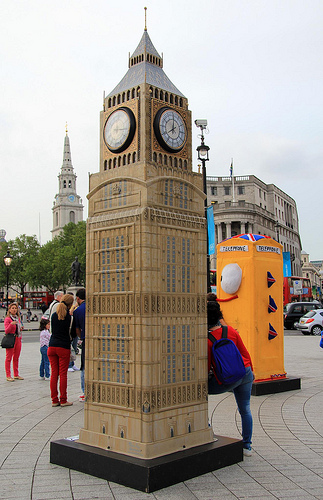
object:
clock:
[153, 105, 189, 154]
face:
[216, 236, 252, 356]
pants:
[46, 345, 71, 406]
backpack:
[207, 325, 246, 393]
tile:
[0, 462, 36, 471]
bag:
[0, 324, 17, 351]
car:
[294, 306, 323, 337]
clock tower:
[49, 3, 245, 495]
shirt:
[39, 329, 51, 348]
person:
[206, 300, 256, 460]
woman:
[46, 294, 73, 409]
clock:
[102, 107, 137, 154]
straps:
[207, 331, 218, 345]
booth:
[215, 231, 302, 399]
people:
[3, 301, 24, 383]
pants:
[4, 335, 23, 379]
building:
[50, 120, 85, 246]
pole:
[201, 160, 213, 293]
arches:
[146, 175, 207, 214]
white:
[220, 262, 243, 295]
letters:
[222, 246, 225, 252]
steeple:
[58, 120, 76, 173]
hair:
[55, 294, 74, 322]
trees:
[33, 233, 62, 296]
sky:
[0, 0, 323, 262]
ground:
[0, 328, 323, 500]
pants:
[80, 339, 86, 395]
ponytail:
[56, 301, 69, 322]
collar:
[208, 321, 222, 329]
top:
[48, 306, 71, 349]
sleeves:
[69, 315, 74, 342]